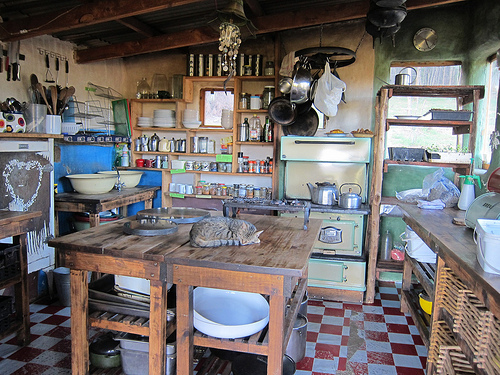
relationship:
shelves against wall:
[124, 73, 279, 209] [117, 4, 478, 308]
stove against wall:
[276, 134, 371, 294] [117, 4, 478, 308]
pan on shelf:
[418, 107, 473, 124] [365, 82, 486, 306]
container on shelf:
[422, 144, 473, 168] [365, 82, 486, 306]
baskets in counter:
[426, 263, 499, 375] [397, 210, 499, 374]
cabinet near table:
[0, 134, 56, 276] [0, 206, 45, 351]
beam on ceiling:
[2, 0, 189, 41] [1, 0, 483, 66]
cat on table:
[189, 220, 263, 251] [46, 216, 326, 375]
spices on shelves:
[236, 146, 273, 175] [124, 73, 279, 209]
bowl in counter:
[411, 289, 435, 317] [397, 210, 499, 374]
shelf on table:
[189, 284, 304, 355] [46, 216, 326, 375]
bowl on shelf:
[188, 286, 270, 341] [189, 284, 304, 355]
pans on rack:
[266, 82, 318, 146] [283, 31, 363, 71]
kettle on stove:
[305, 180, 339, 207] [276, 134, 371, 294]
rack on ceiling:
[283, 31, 363, 71] [1, 0, 483, 66]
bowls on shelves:
[218, 107, 236, 132] [124, 73, 279, 209]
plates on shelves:
[154, 105, 178, 130] [124, 73, 279, 209]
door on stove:
[310, 214, 361, 255] [276, 134, 371, 294]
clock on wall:
[409, 25, 442, 55] [117, 4, 478, 308]